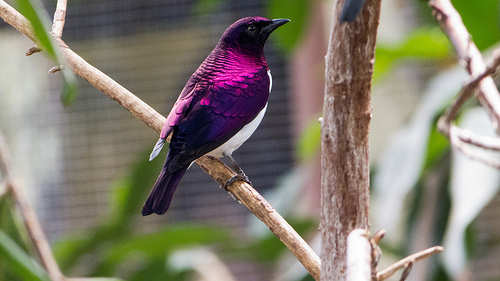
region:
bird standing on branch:
[139, 12, 291, 215]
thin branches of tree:
[13, 6, 491, 275]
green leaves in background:
[0, 8, 492, 276]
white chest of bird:
[215, 70, 272, 160]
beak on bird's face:
[265, 15, 292, 33]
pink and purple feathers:
[200, 47, 268, 118]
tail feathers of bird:
[142, 166, 184, 216]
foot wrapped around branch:
[220, 171, 252, 201]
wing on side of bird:
[188, 72, 271, 147]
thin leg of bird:
[225, 152, 243, 179]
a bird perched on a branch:
[135, 10, 294, 218]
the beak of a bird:
[265, 13, 292, 34]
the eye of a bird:
[243, 19, 260, 36]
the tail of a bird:
[137, 163, 190, 220]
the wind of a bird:
[146, 83, 204, 160]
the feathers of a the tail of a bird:
[138, 162, 185, 222]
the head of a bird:
[223, 11, 291, 49]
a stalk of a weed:
[315, 7, 384, 279]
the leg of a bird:
[221, 150, 252, 192]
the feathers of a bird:
[211, 53, 247, 93]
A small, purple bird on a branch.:
[139, 15, 291, 223]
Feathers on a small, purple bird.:
[201, 72, 257, 115]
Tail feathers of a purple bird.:
[138, 166, 185, 216]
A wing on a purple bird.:
[166, 65, 268, 172]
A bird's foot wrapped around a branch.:
[221, 149, 255, 191]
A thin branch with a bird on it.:
[4, 7, 319, 276]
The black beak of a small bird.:
[261, 15, 291, 34]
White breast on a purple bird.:
[202, 69, 273, 162]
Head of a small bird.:
[216, 9, 293, 51]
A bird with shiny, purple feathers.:
[141, 15, 293, 217]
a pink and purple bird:
[119, 19, 319, 223]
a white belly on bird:
[201, 58, 282, 174]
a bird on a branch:
[80, 1, 331, 251]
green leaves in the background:
[49, 159, 284, 280]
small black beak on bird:
[268, 12, 293, 31]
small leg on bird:
[221, 152, 275, 224]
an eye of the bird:
[236, 20, 263, 40]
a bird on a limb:
[115, 8, 324, 225]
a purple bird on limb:
[120, 10, 313, 250]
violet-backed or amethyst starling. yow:
[126, 11, 299, 227]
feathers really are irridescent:
[147, 35, 285, 140]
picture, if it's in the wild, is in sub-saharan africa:
[0, 1, 499, 278]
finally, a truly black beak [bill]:
[238, 10, 294, 42]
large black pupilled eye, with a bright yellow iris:
[235, 15, 260, 35]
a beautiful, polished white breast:
[200, 66, 279, 163]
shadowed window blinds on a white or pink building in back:
[2, 0, 317, 280]